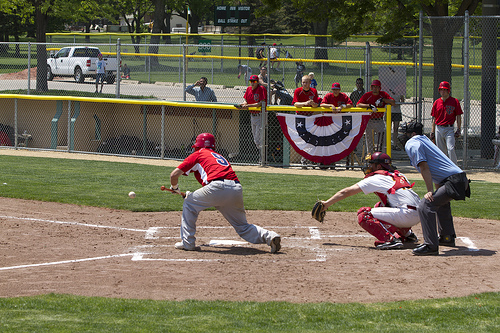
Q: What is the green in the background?
A: Leaves of trees.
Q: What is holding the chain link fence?
A: Poles.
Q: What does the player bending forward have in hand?
A: A bat.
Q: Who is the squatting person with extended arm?
A: A catcher.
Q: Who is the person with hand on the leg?
A: The umpire.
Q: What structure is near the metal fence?
A: A dugout.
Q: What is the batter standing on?
A: Dirt.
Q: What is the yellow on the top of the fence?
A: A line.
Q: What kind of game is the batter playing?
A: Baseball.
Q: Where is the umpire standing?
A: Behind the catcher.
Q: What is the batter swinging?
A: Baseball bat.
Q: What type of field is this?
A: Baseball field.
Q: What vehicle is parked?
A: White truck.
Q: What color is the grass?
A: Green.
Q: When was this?
A: Daytime.